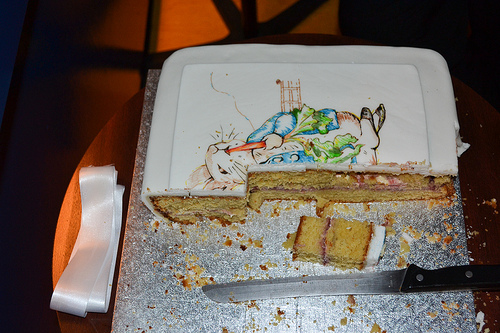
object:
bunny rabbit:
[188, 102, 386, 191]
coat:
[246, 107, 358, 162]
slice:
[293, 215, 385, 268]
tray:
[141, 43, 459, 196]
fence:
[276, 79, 303, 112]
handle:
[401, 263, 500, 292]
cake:
[294, 213, 386, 265]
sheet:
[109, 67, 481, 333]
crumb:
[153, 221, 160, 229]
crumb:
[222, 236, 232, 247]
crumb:
[254, 237, 264, 248]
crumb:
[185, 254, 199, 262]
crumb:
[259, 265, 267, 271]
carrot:
[226, 141, 266, 153]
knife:
[200, 262, 497, 302]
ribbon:
[51, 164, 125, 317]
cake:
[140, 44, 468, 224]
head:
[183, 139, 249, 191]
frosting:
[142, 43, 459, 222]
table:
[48, 32, 500, 331]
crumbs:
[170, 254, 217, 290]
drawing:
[185, 70, 386, 193]